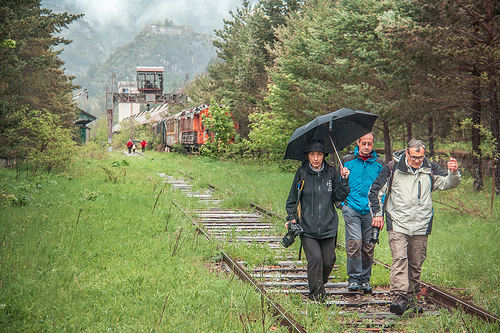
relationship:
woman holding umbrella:
[283, 142, 349, 298] [284, 109, 377, 155]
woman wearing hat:
[283, 142, 349, 298] [303, 137, 330, 153]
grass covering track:
[182, 238, 271, 270] [175, 181, 283, 242]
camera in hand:
[280, 219, 305, 250] [280, 217, 298, 230]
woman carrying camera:
[283, 142, 349, 298] [280, 219, 305, 250]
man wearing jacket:
[343, 132, 386, 290] [343, 152, 387, 216]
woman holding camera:
[283, 142, 349, 298] [280, 219, 305, 250]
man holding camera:
[370, 139, 464, 300] [369, 226, 387, 246]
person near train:
[139, 141, 149, 152] [151, 107, 231, 155]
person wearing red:
[139, 141, 149, 152] [139, 139, 147, 144]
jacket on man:
[343, 152, 387, 216] [343, 132, 386, 290]